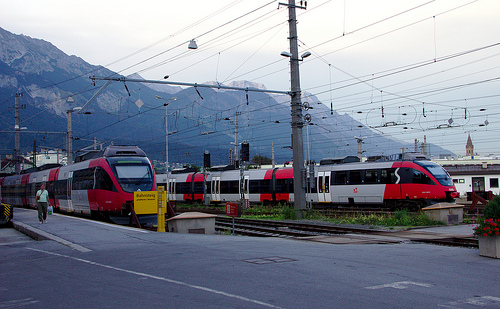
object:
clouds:
[80, 7, 380, 67]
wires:
[0, 0, 499, 123]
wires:
[296, 0, 490, 64]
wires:
[311, 116, 500, 136]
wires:
[71, 100, 291, 143]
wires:
[300, 43, 498, 98]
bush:
[468, 192, 499, 236]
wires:
[0, 1, 499, 167]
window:
[116, 166, 152, 179]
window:
[426, 166, 448, 175]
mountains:
[3, 29, 455, 171]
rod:
[88, 75, 297, 98]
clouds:
[361, 13, 462, 80]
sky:
[333, 12, 472, 97]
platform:
[11, 202, 156, 249]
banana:
[0, 29, 236, 79]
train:
[155, 157, 460, 203]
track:
[306, 203, 426, 213]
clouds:
[61, 4, 198, 38]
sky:
[2, 8, 497, 166]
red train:
[155, 151, 461, 212]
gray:
[332, 185, 380, 196]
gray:
[208, 170, 260, 201]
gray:
[167, 172, 185, 200]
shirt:
[35, 182, 51, 203]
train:
[0, 145, 156, 225]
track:
[171, 217, 299, 249]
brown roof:
[165, 212, 218, 223]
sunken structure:
[165, 212, 217, 235]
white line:
[23, 244, 280, 307]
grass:
[335, 213, 393, 222]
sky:
[322, 11, 412, 69]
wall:
[0, 26, 272, 174]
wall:
[173, 81, 315, 167]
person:
[35, 184, 50, 225]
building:
[431, 155, 500, 197]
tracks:
[242, 212, 343, 237]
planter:
[477, 236, 500, 261]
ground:
[3, 262, 499, 308]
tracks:
[241, 201, 478, 253]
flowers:
[467, 214, 500, 237]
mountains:
[1, 25, 454, 191]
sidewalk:
[14, 196, 155, 246]